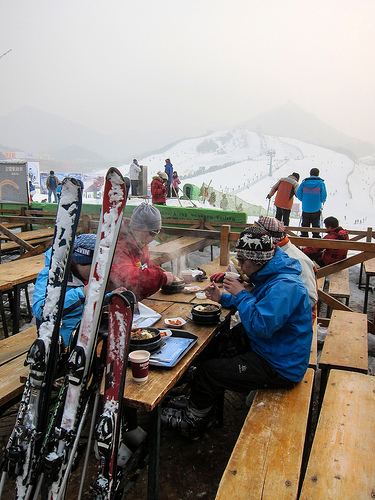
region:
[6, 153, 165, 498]
skies leaning on table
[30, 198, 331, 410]
four people at the table eating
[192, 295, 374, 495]
four wood benches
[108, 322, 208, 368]
a tray with a dish of food on it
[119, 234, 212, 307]
steam from the hot food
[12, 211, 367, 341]
wood fence between tables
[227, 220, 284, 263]
stocking hat with a reindeer on it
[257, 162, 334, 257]
two men looking out at the mountains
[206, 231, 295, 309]
person drinking out a small white cup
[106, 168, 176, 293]
two people wearing a red jacket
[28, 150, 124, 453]
Skis leaning up against the table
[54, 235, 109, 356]
Snow on the skis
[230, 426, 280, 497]
Wooden bench is cracked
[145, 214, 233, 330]
People are eating hot food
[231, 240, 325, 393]
Woman wearing blue jacket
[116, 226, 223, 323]
Steam coming off of food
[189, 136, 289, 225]
Ski drop that you go down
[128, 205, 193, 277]
Woman is wearing a beanie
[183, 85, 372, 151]
Hill in the background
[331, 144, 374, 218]
Fence along the road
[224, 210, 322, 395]
people sitting on wood bench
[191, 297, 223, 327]
bowl of food on table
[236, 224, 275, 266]
knit cap on head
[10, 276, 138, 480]
skis leaning against table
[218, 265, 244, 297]
hand holding cup to face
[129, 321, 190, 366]
bowl of food on tray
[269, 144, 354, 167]
snow on ski slope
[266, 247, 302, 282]
hood on blue jacket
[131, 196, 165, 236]
gray cap on head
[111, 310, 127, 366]
snow on red ski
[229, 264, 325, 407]
man's jacket is blue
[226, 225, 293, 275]
man is wearing a hat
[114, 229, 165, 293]
person's jacket is red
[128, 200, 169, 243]
person wearing a hat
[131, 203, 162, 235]
the hat is gray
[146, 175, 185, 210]
woman wearing red jacket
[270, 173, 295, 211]
woman wearing orange jacket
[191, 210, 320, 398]
the man is drinking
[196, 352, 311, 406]
man's pants are black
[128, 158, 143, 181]
man's jacket is white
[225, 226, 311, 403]
man eating at a picnic table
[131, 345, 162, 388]
cup on the table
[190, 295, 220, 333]
bowl on the table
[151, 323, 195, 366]
tray on the table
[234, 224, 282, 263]
hat on man's head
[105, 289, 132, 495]
ski leaning on table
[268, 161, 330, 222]
two skiers at the top of a hill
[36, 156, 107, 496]
skis leaning on a table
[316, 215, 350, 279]
man sitting on a bench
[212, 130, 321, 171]
ski hill in the background